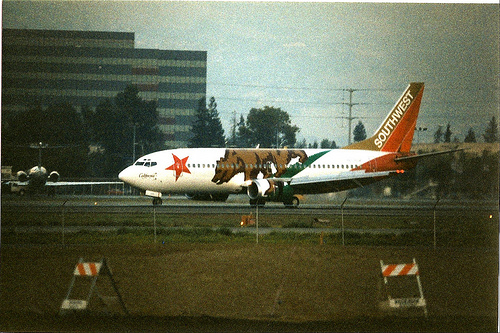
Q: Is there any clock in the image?
A: No, there are no clocks.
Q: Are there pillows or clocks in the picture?
A: No, there are no clocks or pillows.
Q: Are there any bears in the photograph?
A: Yes, there is a bear.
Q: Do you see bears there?
A: Yes, there is a bear.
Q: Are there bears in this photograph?
A: Yes, there is a bear.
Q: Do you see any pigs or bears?
A: Yes, there is a bear.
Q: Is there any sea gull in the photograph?
A: No, there are no seagulls.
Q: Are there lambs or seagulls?
A: No, there are no seagulls or lambs.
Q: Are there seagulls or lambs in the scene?
A: No, there are no seagulls or lambs.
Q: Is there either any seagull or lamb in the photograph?
A: No, there are no seagulls or lambs.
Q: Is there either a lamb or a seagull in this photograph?
A: No, there are no seagulls or lambs.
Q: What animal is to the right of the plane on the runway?
A: The animal is a bear.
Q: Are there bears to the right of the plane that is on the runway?
A: Yes, there is a bear to the right of the plane.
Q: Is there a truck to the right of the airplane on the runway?
A: No, there is a bear to the right of the airplane.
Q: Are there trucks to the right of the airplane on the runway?
A: No, there is a bear to the right of the airplane.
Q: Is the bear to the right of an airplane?
A: Yes, the bear is to the right of an airplane.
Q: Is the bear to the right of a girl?
A: No, the bear is to the right of an airplane.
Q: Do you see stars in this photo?
A: Yes, there is a star.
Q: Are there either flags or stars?
A: Yes, there is a star.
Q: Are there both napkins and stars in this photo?
A: No, there is a star but no napkins.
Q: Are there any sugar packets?
A: No, there are no sugar packets.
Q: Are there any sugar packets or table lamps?
A: No, there are no sugar packets or table lamps.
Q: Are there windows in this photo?
A: Yes, there are windows.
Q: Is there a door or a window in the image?
A: Yes, there are windows.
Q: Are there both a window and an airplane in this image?
A: Yes, there are both a window and an airplane.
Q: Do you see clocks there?
A: No, there are no clocks.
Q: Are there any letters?
A: Yes, there are letters.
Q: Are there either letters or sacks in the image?
A: Yes, there are letters.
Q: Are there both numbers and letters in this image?
A: No, there are letters but no numbers.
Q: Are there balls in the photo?
A: No, there are no balls.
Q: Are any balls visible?
A: No, there are no balls.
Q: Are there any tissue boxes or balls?
A: No, there are no balls or tissue boxes.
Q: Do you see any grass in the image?
A: Yes, there is grass.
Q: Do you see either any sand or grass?
A: Yes, there is grass.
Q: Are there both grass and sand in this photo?
A: No, there is grass but no sand.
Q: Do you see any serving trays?
A: No, there are no serving trays.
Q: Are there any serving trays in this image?
A: No, there are no serving trays.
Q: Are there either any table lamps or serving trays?
A: No, there are no serving trays or table lamps.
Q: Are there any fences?
A: Yes, there is a fence.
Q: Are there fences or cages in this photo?
A: Yes, there is a fence.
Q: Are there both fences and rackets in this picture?
A: No, there is a fence but no rackets.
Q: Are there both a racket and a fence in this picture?
A: No, there is a fence but no rackets.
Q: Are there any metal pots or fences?
A: Yes, there is a metal fence.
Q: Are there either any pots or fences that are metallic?
A: Yes, the fence is metallic.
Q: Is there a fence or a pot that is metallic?
A: Yes, the fence is metallic.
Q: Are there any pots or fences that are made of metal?
A: Yes, the fence is made of metal.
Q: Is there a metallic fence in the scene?
A: Yes, there is a metal fence.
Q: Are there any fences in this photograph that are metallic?
A: Yes, there is a fence that is metallic.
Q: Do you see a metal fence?
A: Yes, there is a fence that is made of metal.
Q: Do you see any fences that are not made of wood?
A: Yes, there is a fence that is made of metal.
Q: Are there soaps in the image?
A: No, there are no soaps.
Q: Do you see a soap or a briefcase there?
A: No, there are no soaps or briefcases.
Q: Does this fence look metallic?
A: Yes, the fence is metallic.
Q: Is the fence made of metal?
A: Yes, the fence is made of metal.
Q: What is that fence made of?
A: The fence is made of metal.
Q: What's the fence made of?
A: The fence is made of metal.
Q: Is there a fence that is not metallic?
A: No, there is a fence but it is metallic.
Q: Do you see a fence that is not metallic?
A: No, there is a fence but it is metallic.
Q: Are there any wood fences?
A: No, there is a fence but it is made of metal.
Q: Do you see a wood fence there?
A: No, there is a fence but it is made of metal.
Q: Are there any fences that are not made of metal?
A: No, there is a fence but it is made of metal.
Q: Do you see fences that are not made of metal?
A: No, there is a fence but it is made of metal.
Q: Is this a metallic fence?
A: Yes, this is a metallic fence.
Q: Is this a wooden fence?
A: No, this is a metallic fence.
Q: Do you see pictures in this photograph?
A: No, there are no pictures.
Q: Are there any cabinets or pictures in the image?
A: No, there are no pictures or cabinets.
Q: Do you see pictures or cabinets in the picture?
A: No, there are no pictures or cabinets.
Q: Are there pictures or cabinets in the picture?
A: No, there are no pictures or cabinets.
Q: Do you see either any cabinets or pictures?
A: No, there are no pictures or cabinets.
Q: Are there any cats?
A: No, there are no cats.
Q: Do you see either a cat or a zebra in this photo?
A: No, there are no cats or zebras.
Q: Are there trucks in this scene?
A: No, there are no trucks.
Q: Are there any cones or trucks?
A: No, there are no trucks or cones.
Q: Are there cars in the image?
A: No, there are no cars.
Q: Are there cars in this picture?
A: No, there are no cars.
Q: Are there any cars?
A: No, there are no cars.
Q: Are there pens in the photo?
A: No, there are no pens.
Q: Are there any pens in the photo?
A: No, there are no pens.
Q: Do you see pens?
A: No, there are no pens.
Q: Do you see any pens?
A: No, there are no pens.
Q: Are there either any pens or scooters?
A: No, there are no pens or scooters.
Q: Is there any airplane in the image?
A: Yes, there is an airplane.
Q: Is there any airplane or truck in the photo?
A: Yes, there is an airplane.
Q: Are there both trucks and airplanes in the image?
A: No, there is an airplane but no trucks.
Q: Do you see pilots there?
A: No, there are no pilots.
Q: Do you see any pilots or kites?
A: No, there are no pilots or kites.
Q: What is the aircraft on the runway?
A: The aircraft is an airplane.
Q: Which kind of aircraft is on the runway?
A: The aircraft is an airplane.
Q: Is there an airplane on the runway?
A: Yes, there is an airplane on the runway.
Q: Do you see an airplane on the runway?
A: Yes, there is an airplane on the runway.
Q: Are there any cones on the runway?
A: No, there is an airplane on the runway.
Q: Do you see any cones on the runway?
A: No, there is an airplane on the runway.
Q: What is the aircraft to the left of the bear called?
A: The aircraft is an airplane.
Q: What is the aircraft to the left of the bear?
A: The aircraft is an airplane.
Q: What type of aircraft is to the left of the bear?
A: The aircraft is an airplane.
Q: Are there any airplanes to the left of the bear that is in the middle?
A: Yes, there is an airplane to the left of the bear.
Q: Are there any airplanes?
A: Yes, there is an airplane.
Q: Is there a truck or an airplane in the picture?
A: Yes, there is an airplane.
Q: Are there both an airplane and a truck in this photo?
A: No, there is an airplane but no trucks.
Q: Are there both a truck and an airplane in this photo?
A: No, there is an airplane but no trucks.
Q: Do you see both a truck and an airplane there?
A: No, there is an airplane but no trucks.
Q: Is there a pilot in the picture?
A: No, there are no pilots.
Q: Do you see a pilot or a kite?
A: No, there are no pilots or kites.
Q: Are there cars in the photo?
A: No, there are no cars.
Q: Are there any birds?
A: No, there are no birds.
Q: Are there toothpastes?
A: No, there are no toothpastes.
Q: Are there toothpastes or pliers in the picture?
A: No, there are no toothpastes or pliers.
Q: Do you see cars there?
A: No, there are no cars.